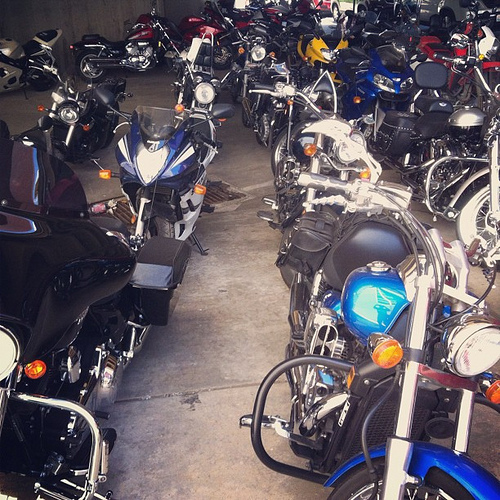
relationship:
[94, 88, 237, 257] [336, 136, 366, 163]
cycle has light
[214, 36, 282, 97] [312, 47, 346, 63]
motorcycle has light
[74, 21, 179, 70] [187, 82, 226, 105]
motorcycle has light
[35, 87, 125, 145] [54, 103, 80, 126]
motorcycle has light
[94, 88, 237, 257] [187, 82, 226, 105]
cycle has light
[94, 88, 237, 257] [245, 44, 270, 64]
cycle has light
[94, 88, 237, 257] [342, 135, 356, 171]
cycle has headlight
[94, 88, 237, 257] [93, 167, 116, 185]
cycle has turn signal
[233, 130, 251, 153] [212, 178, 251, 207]
floor has drain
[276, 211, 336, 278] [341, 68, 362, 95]
box on right side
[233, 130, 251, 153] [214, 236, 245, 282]
floor has dirt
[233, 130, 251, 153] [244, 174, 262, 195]
floor has crack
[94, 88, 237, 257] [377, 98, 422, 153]
cycle has storage box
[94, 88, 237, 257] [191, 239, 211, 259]
cycle has kickstand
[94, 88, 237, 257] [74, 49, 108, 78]
cycle has rear tire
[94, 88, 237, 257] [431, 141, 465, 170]
cycle has side engine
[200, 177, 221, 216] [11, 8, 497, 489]
grate in photo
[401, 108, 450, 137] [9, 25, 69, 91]
saddlebags on bike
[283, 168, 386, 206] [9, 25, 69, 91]
sissy bar on bike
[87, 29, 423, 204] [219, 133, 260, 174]
motorcycles on street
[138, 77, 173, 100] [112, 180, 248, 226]
ground has drain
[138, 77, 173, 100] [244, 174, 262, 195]
ground has crack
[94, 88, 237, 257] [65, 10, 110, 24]
cycle by wall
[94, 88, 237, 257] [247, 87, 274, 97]
cycle has handle